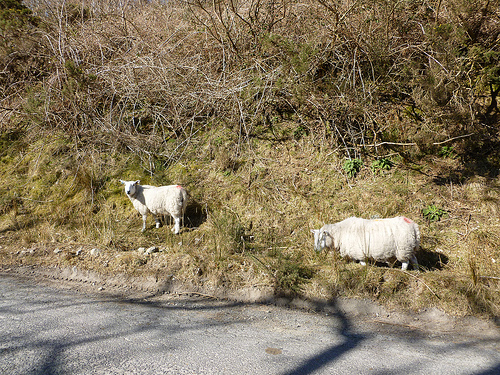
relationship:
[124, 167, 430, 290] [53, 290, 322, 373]
sheep by road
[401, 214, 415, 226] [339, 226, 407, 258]
mark on fur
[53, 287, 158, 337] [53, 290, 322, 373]
shadows on road